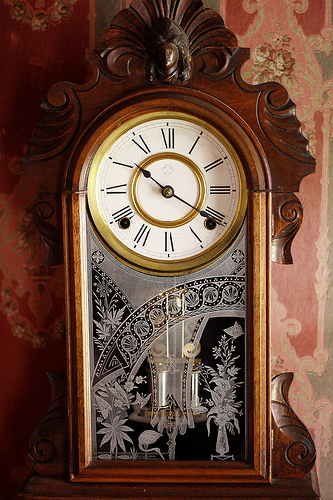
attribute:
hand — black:
[171, 194, 216, 223]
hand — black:
[133, 162, 162, 189]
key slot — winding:
[118, 216, 130, 228]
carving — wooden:
[44, 30, 317, 171]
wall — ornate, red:
[11, 8, 326, 484]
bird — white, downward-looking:
[137, 431, 166, 460]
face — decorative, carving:
[142, 16, 206, 97]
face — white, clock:
[94, 118, 242, 262]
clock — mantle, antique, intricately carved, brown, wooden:
[18, 0, 319, 499]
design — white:
[97, 252, 238, 456]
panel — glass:
[82, 218, 248, 462]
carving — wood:
[93, 0, 239, 86]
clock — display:
[84, 109, 251, 463]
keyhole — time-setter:
[202, 216, 217, 230]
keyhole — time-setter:
[117, 215, 132, 230]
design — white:
[91, 273, 243, 458]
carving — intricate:
[271, 367, 315, 475]